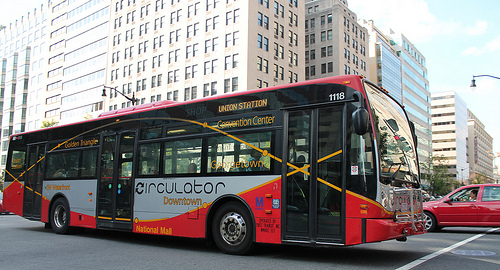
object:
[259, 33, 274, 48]
window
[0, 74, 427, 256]
bus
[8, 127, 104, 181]
side windows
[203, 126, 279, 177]
windows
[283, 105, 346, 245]
side doors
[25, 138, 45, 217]
rear side door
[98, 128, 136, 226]
center door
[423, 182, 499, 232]
car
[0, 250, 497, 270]
street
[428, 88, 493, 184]
building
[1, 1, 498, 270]
city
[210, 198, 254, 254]
large tire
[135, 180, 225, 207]
writting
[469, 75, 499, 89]
street light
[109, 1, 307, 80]
building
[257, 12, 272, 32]
windows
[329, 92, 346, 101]
id number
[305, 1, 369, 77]
buildings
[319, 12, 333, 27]
windows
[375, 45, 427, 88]
glass windows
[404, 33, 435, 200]
highrise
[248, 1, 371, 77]
building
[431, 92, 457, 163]
windows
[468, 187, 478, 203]
person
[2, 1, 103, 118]
building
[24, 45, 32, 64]
windows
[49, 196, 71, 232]
rear tire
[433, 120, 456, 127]
windows